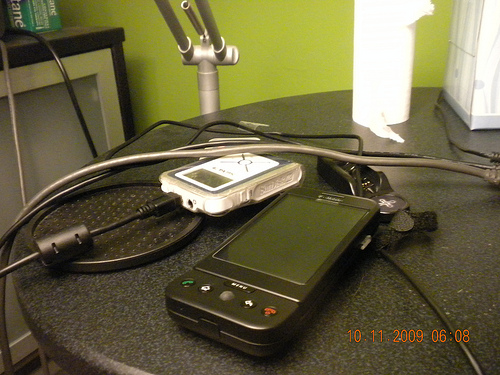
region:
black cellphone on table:
[162, 180, 387, 355]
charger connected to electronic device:
[19, 182, 191, 282]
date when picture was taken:
[344, 317, 476, 355]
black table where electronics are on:
[457, 181, 498, 331]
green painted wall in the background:
[246, 2, 349, 77]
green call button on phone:
[177, 275, 200, 295]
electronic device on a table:
[149, 135, 308, 222]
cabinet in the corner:
[0, 25, 142, 162]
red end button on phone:
[262, 301, 280, 326]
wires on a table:
[119, 113, 493, 165]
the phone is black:
[168, 215, 272, 315]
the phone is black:
[222, 225, 283, 362]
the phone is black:
[205, 226, 265, 323]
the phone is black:
[228, 176, 290, 286]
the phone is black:
[268, 195, 383, 346]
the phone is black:
[223, 292, 261, 369]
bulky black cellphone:
[143, 183, 388, 359]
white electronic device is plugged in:
[18, 127, 348, 278]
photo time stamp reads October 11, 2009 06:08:
[341, 315, 479, 353]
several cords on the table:
[11, 25, 148, 302]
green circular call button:
[173, 266, 203, 305]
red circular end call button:
[256, 297, 284, 339]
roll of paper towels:
[343, 1, 455, 151]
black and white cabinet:
[5, 7, 152, 367]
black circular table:
[11, 52, 496, 373]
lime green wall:
[110, 2, 466, 109]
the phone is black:
[185, 139, 405, 349]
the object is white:
[161, 128, 298, 223]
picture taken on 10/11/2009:
[335, 316, 431, 362]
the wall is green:
[56, 0, 491, 165]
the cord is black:
[0, 180, 178, 296]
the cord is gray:
[303, 143, 491, 213]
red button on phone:
[248, 295, 276, 325]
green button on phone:
[172, 270, 193, 295]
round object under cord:
[22, 167, 185, 275]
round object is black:
[18, 170, 207, 290]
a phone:
[159, 136, 331, 339]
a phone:
[230, 236, 325, 336]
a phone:
[223, 127, 387, 318]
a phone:
[226, 213, 325, 299]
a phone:
[237, 186, 359, 336]